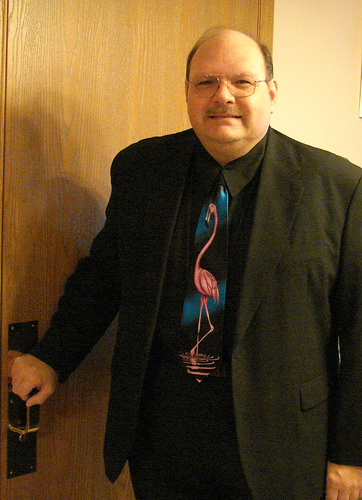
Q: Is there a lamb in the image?
A: No, there are no lambs.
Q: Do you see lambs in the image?
A: No, there are no lambs.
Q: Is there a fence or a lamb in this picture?
A: No, there are no lambs or fences.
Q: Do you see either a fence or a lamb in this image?
A: No, there are no lambs or fences.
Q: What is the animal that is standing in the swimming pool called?
A: The animal is a flamingo.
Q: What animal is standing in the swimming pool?
A: The animal is a flamingo.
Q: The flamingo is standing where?
A: The flamingo is standing in the pool.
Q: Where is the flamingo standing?
A: The flamingo is standing in the pool.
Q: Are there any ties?
A: Yes, there is a tie.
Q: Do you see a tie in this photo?
A: Yes, there is a tie.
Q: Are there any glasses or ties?
A: Yes, there is a tie.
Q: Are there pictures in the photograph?
A: No, there are no pictures.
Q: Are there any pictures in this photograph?
A: No, there are no pictures.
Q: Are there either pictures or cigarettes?
A: No, there are no pictures or cigarettes.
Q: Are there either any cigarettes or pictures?
A: No, there are no pictures or cigarettes.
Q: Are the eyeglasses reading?
A: Yes, the eyeglasses are reading.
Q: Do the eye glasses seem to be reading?
A: Yes, the eye glasses are reading.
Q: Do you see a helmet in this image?
A: No, there are no helmets.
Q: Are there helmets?
A: No, there are no helmets.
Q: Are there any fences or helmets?
A: No, there are no helmets or fences.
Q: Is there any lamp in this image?
A: No, there are no lamps.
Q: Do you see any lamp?
A: No, there are no lamps.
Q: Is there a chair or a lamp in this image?
A: No, there are no lamps or chairs.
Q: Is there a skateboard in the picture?
A: No, there are no skateboards.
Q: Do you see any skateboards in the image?
A: No, there are no skateboards.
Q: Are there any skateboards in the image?
A: No, there are no skateboards.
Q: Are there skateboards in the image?
A: No, there are no skateboards.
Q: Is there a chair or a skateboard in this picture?
A: No, there are no skateboards or chairs.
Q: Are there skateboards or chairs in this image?
A: No, there are no skateboards or chairs.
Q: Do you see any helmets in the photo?
A: No, there are no helmets.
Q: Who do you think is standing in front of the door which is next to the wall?
A: The man is standing in front of the door.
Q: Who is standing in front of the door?
A: The man is standing in front of the door.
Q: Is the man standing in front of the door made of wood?
A: Yes, the man is standing in front of the door.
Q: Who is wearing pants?
A: The man is wearing pants.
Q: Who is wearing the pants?
A: The man is wearing pants.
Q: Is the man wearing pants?
A: Yes, the man is wearing pants.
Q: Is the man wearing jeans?
A: No, the man is wearing pants.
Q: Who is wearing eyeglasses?
A: The man is wearing eyeglasses.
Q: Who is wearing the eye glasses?
A: The man is wearing eyeglasses.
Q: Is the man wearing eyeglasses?
A: Yes, the man is wearing eyeglasses.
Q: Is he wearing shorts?
A: No, the man is wearing eyeglasses.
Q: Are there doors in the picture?
A: Yes, there is a door.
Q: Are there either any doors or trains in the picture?
A: Yes, there is a door.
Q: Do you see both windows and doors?
A: No, there is a door but no windows.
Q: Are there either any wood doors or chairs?
A: Yes, there is a wood door.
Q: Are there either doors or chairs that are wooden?
A: Yes, the door is wooden.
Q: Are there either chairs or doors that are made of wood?
A: Yes, the door is made of wood.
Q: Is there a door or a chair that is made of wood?
A: Yes, the door is made of wood.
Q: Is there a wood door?
A: Yes, there is a door that is made of wood.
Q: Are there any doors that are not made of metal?
A: Yes, there is a door that is made of wood.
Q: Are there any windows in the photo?
A: No, there are no windows.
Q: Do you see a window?
A: No, there are no windows.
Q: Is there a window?
A: No, there are no windows.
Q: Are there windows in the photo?
A: No, there are no windows.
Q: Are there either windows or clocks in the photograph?
A: No, there are no windows or clocks.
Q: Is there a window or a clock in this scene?
A: No, there are no windows or clocks.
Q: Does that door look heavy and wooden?
A: Yes, the door is heavy and wooden.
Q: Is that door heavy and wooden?
A: Yes, the door is heavy and wooden.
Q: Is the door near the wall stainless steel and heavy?
A: No, the door is heavy but wooden.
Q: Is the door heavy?
A: Yes, the door is heavy.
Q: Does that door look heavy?
A: Yes, the door is heavy.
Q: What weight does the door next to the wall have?
A: The door has heavy weight.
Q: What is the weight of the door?
A: The door is heavy.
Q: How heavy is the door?
A: The door is heavy.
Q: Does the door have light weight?
A: No, the door is heavy.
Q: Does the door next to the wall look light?
A: No, the door is heavy.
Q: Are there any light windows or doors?
A: No, there is a door but it is heavy.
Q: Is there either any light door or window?
A: No, there is a door but it is heavy.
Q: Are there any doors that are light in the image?
A: No, there is a door but it is heavy.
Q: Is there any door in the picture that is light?
A: No, there is a door but it is heavy.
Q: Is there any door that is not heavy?
A: No, there is a door but it is heavy.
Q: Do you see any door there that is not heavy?
A: No, there is a door but it is heavy.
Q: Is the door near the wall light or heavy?
A: The door is heavy.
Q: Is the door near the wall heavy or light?
A: The door is heavy.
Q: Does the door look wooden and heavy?
A: Yes, the door is wooden and heavy.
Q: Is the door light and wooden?
A: No, the door is wooden but heavy.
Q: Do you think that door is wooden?
A: Yes, the door is wooden.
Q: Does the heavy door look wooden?
A: Yes, the door is wooden.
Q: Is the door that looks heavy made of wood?
A: Yes, the door is made of wood.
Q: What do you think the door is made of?
A: The door is made of wood.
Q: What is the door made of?
A: The door is made of wood.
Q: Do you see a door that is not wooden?
A: No, there is a door but it is wooden.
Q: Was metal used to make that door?
A: No, the door is made of wood.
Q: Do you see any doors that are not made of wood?
A: No, there is a door but it is made of wood.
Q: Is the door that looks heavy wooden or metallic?
A: The door is wooden.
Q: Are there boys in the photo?
A: No, there are no boys.